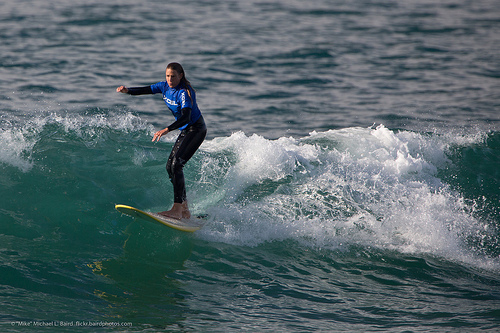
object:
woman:
[114, 62, 206, 220]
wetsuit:
[125, 82, 207, 205]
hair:
[167, 62, 194, 89]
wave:
[0, 110, 500, 277]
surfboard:
[113, 204, 202, 233]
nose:
[168, 76, 173, 82]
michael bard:
[29, 319, 73, 327]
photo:
[0, 0, 500, 333]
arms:
[169, 88, 194, 134]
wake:
[190, 124, 500, 276]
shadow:
[85, 217, 193, 331]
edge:
[115, 204, 202, 233]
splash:
[0, 107, 500, 279]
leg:
[172, 118, 207, 203]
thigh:
[171, 122, 208, 162]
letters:
[166, 99, 172, 105]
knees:
[170, 160, 185, 173]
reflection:
[82, 217, 194, 328]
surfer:
[116, 61, 208, 220]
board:
[114, 203, 204, 233]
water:
[0, 0, 500, 333]